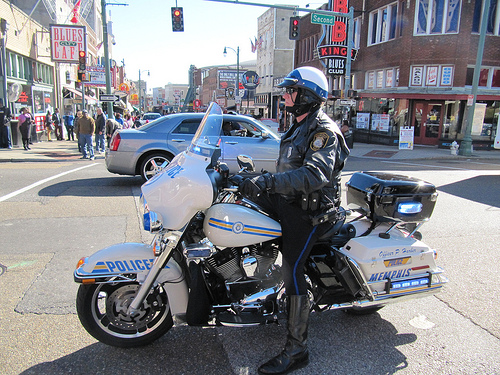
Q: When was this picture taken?
A: Daytime.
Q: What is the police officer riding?
A: Motorcycle.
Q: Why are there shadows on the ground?
A: It's sunny.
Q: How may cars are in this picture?
A: 1.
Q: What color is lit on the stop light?
A: Red.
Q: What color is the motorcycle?
A: White.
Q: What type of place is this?
A: City.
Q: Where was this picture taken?
A: Memphis.